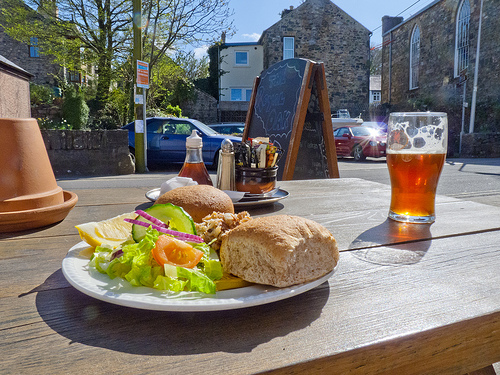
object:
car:
[333, 125, 386, 162]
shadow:
[17, 267, 331, 357]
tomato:
[151, 234, 204, 268]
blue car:
[119, 116, 243, 170]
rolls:
[194, 210, 254, 252]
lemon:
[74, 211, 138, 248]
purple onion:
[122, 209, 204, 244]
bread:
[220, 214, 341, 288]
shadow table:
[348, 217, 433, 266]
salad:
[83, 202, 224, 295]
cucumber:
[131, 202, 197, 243]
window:
[235, 50, 249, 65]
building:
[206, 42, 264, 124]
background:
[158, 85, 467, 206]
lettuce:
[87, 217, 224, 296]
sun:
[368, 126, 382, 139]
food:
[74, 184, 341, 296]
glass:
[385, 111, 449, 224]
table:
[0, 177, 500, 375]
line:
[338, 227, 499, 252]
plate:
[60, 210, 339, 314]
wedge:
[74, 210, 140, 249]